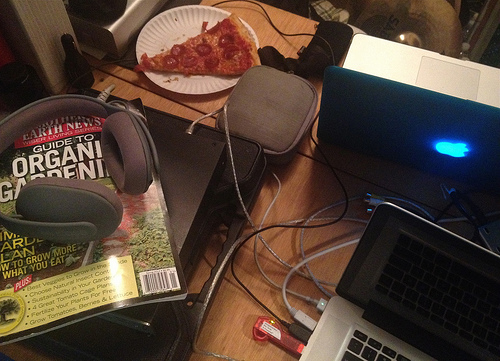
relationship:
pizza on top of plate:
[131, 12, 262, 76] [134, 5, 260, 95]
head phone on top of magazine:
[0, 93, 161, 244] [1, 96, 189, 347]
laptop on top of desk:
[296, 200, 500, 360] [0, 0, 499, 360]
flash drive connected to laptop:
[251, 315, 307, 359] [296, 200, 500, 360]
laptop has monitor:
[296, 200, 500, 360] [336, 200, 499, 360]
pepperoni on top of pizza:
[196, 41, 212, 56] [131, 12, 262, 76]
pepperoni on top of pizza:
[221, 45, 240, 61] [131, 12, 262, 76]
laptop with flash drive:
[296, 200, 500, 360] [251, 315, 307, 359]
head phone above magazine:
[0, 93, 161, 244] [1, 96, 189, 347]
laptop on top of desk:
[314, 31, 497, 191] [0, 0, 499, 360]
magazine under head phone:
[1, 96, 189, 347] [0, 93, 161, 244]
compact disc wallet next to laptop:
[215, 64, 320, 165] [314, 31, 497, 191]